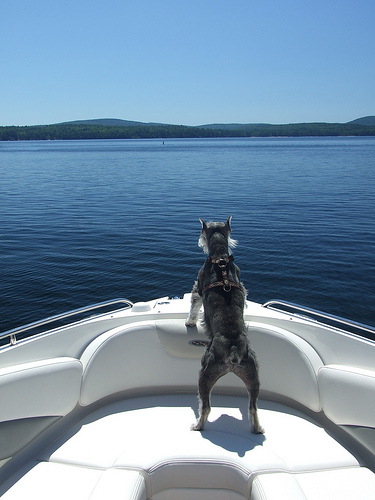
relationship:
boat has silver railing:
[1, 285, 367, 499] [1, 293, 141, 348]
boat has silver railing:
[1, 285, 367, 499] [260, 296, 374, 339]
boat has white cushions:
[1, 285, 367, 499] [0, 321, 373, 498]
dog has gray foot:
[184, 214, 268, 437] [191, 421, 211, 433]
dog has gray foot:
[184, 214, 268, 437] [250, 425, 264, 438]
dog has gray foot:
[184, 214, 268, 437] [184, 311, 200, 328]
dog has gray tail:
[184, 214, 268, 437] [222, 330, 254, 366]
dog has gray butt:
[184, 214, 268, 437] [209, 330, 251, 361]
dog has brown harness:
[184, 214, 268, 437] [197, 253, 250, 295]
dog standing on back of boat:
[184, 214, 268, 437] [1, 285, 367, 499]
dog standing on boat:
[184, 214, 268, 437] [1, 285, 367, 499]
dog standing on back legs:
[184, 214, 268, 437] [187, 373, 269, 439]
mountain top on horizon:
[0, 115, 375, 141] [1, 113, 374, 151]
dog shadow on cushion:
[189, 401, 271, 461] [0, 321, 373, 498]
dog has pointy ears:
[184, 214, 268, 437] [195, 213, 237, 231]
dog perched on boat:
[184, 214, 268, 437] [1, 285, 367, 499]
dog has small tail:
[184, 214, 268, 437] [222, 330, 254, 366]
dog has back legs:
[184, 214, 268, 437] [187, 373, 269, 439]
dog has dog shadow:
[184, 214, 268, 437] [189, 401, 271, 461]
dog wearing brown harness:
[184, 214, 268, 437] [197, 253, 250, 295]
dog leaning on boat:
[184, 214, 268, 437] [1, 285, 367, 499]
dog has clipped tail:
[184, 214, 268, 437] [228, 320, 252, 369]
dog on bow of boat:
[184, 214, 268, 437] [1, 285, 367, 499]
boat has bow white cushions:
[1, 285, 367, 499] [0, 321, 373, 498]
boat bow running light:
[1, 285, 367, 499] [2, 143, 370, 367]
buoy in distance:
[158, 136, 167, 146] [4, 124, 371, 137]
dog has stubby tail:
[184, 214, 268, 437] [222, 330, 254, 366]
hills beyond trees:
[68, 116, 374, 126] [2, 124, 373, 137]